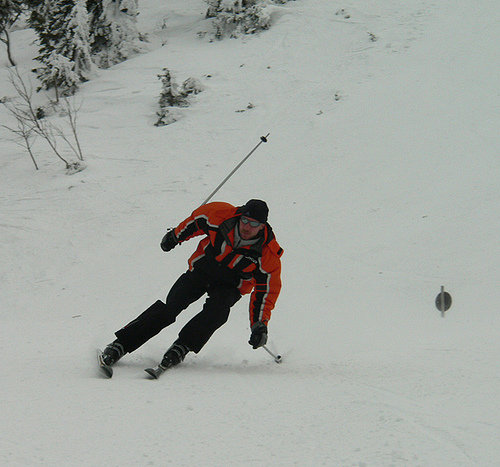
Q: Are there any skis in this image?
A: Yes, there are skis.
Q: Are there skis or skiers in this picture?
A: Yes, there are skis.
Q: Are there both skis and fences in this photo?
A: No, there are skis but no fences.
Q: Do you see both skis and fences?
A: No, there are skis but no fences.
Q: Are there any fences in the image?
A: No, there are no fences.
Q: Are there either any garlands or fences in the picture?
A: No, there are no fences or garlands.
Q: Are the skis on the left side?
A: Yes, the skis are on the left of the image.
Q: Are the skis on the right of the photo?
A: No, the skis are on the left of the image.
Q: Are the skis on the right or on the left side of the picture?
A: The skis are on the left of the image.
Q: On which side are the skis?
A: The skis are on the left of the image.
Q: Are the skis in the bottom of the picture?
A: Yes, the skis are in the bottom of the image.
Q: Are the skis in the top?
A: No, the skis are in the bottom of the image.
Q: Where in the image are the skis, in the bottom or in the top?
A: The skis are in the bottom of the image.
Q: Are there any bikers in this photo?
A: No, there are no bikers.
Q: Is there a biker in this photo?
A: No, there are no bikers.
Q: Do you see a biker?
A: No, there are no bikers.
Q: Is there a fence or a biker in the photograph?
A: No, there are no bikers or fences.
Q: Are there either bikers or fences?
A: No, there are no bikers or fences.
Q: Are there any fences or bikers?
A: No, there are no bikers or fences.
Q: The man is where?
A: The man is in the snow.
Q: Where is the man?
A: The man is in the snow.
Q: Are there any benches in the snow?
A: No, there is a man in the snow.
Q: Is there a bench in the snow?
A: No, there is a man in the snow.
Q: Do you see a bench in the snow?
A: No, there is a man in the snow.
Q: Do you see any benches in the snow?
A: No, there is a man in the snow.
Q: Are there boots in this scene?
A: Yes, there are boots.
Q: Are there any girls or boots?
A: Yes, there are boots.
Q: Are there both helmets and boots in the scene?
A: No, there are boots but no helmets.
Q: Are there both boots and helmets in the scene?
A: No, there are boots but no helmets.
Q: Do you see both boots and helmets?
A: No, there are boots but no helmets.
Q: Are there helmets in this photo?
A: No, there are no helmets.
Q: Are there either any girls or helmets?
A: No, there are no helmets or girls.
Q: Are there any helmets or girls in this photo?
A: No, there are no helmets or girls.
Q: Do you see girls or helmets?
A: No, there are no helmets or girls.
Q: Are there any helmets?
A: No, there are no helmets.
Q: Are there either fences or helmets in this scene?
A: No, there are no helmets or fences.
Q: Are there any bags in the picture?
A: No, there are no bags.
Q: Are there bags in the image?
A: No, there are no bags.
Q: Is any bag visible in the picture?
A: No, there are no bags.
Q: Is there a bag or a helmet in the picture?
A: No, there are no bags or helmets.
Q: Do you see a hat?
A: Yes, there is a hat.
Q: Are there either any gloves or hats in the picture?
A: Yes, there is a hat.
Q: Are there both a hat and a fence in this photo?
A: No, there is a hat but no fences.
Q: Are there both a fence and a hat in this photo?
A: No, there is a hat but no fences.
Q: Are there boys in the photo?
A: No, there are no boys.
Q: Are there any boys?
A: No, there are no boys.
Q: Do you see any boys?
A: No, there are no boys.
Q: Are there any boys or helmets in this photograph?
A: No, there are no boys or helmets.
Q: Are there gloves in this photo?
A: Yes, there are gloves.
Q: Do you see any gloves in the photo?
A: Yes, there are gloves.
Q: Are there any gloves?
A: Yes, there are gloves.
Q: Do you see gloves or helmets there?
A: Yes, there are gloves.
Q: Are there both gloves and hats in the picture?
A: Yes, there are both gloves and a hat.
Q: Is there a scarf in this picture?
A: No, there are no scarves.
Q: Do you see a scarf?
A: No, there are no scarves.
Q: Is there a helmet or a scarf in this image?
A: No, there are no scarves or helmets.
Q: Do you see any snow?
A: Yes, there is snow.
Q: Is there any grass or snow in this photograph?
A: Yes, there is snow.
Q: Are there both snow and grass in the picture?
A: No, there is snow but no grass.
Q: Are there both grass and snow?
A: No, there is snow but no grass.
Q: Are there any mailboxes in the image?
A: No, there are no mailboxes.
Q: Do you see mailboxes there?
A: No, there are no mailboxes.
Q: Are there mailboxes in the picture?
A: No, there are no mailboxes.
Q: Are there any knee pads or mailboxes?
A: No, there are no mailboxes or knee pads.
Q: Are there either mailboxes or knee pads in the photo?
A: No, there are no mailboxes or knee pads.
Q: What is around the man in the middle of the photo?
A: The snow is around the man.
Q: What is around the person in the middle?
A: The snow is around the man.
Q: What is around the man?
A: The snow is around the man.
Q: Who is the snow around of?
A: The snow is around the man.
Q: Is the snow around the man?
A: Yes, the snow is around the man.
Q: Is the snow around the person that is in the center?
A: Yes, the snow is around the man.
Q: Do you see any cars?
A: No, there are no cars.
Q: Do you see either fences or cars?
A: No, there are no cars or fences.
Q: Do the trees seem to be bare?
A: Yes, the trees are bare.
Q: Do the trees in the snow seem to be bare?
A: Yes, the trees are bare.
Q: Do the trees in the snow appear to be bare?
A: Yes, the trees are bare.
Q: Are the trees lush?
A: No, the trees are bare.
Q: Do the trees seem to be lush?
A: No, the trees are bare.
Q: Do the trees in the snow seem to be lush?
A: No, the trees are bare.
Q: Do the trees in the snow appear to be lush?
A: No, the trees are bare.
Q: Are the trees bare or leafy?
A: The trees are bare.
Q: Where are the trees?
A: The trees are in the snow.